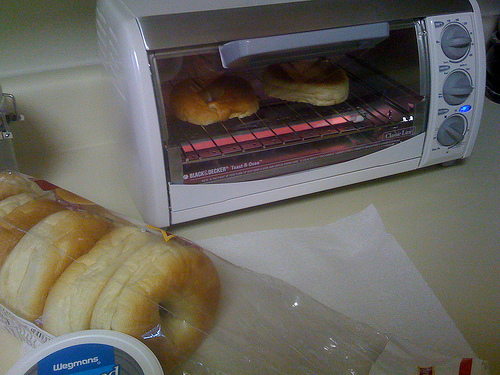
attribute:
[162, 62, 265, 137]
bagel — toasted, fresh, ready to be eaten, ready to be toasted, toasting, split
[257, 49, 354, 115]
bagel — toasted, fresh, ready to be eaten, ready to be toasted, toasting, split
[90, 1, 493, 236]
toaster oven — white, black, branded, decker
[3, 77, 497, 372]
counter top — beige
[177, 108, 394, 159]
light — red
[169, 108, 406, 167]
coil — red, hot, heating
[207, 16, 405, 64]
handle — gray, grey, metal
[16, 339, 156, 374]
label — wegmans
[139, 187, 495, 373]
paper — waxed, white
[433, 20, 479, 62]
knob — grey, gray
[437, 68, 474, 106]
knob — grey, gray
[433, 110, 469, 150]
knob — grey, gray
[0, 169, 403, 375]
bag — plastic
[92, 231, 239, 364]
bagel — present, fresh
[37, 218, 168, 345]
bagel — present, fresh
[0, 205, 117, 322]
bagel — present, fresh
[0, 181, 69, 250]
bagel — present, fresh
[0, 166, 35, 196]
bagel — present, fresh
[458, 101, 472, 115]
light — blue, on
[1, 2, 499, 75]
backsplash — beige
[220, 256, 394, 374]
space — empty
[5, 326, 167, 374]
container — cream cheese